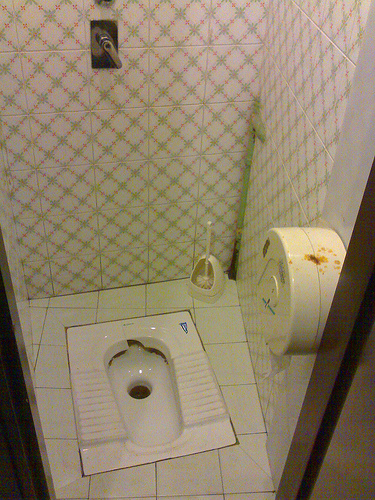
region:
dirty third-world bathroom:
[31, 26, 347, 482]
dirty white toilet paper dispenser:
[256, 199, 358, 375]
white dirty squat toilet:
[56, 302, 234, 471]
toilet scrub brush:
[186, 215, 235, 309]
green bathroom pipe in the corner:
[218, 87, 267, 300]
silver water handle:
[77, 16, 137, 89]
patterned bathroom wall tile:
[16, 72, 188, 248]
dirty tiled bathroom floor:
[28, 278, 273, 494]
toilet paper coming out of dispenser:
[255, 333, 296, 393]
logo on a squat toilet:
[168, 317, 211, 360]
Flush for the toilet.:
[84, 20, 126, 77]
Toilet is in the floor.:
[60, 326, 241, 469]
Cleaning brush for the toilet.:
[190, 218, 229, 304]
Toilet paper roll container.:
[249, 231, 306, 352]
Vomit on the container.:
[284, 224, 346, 293]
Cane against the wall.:
[220, 87, 262, 291]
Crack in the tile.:
[217, 426, 284, 490]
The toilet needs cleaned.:
[89, 335, 173, 371]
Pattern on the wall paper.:
[46, 110, 185, 221]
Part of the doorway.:
[325, 268, 373, 496]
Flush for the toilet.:
[82, 16, 135, 73]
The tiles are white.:
[151, 461, 244, 492]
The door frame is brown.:
[291, 395, 330, 490]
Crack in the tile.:
[234, 436, 273, 493]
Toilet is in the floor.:
[46, 311, 235, 472]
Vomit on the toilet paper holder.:
[287, 244, 349, 289]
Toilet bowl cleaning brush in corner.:
[171, 211, 224, 305]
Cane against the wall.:
[226, 100, 264, 284]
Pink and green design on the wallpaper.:
[54, 110, 167, 194]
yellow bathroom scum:
[285, 234, 342, 283]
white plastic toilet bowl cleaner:
[180, 203, 232, 313]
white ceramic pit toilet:
[49, 295, 257, 492]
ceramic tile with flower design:
[85, 148, 158, 219]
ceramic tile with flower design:
[141, 149, 206, 212]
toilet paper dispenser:
[235, 207, 363, 380]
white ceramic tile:
[191, 328, 262, 391]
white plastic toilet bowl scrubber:
[183, 207, 231, 317]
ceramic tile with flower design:
[95, 239, 153, 296]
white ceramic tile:
[94, 275, 153, 315]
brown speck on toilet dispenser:
[301, 243, 329, 272]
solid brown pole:
[286, 326, 341, 480]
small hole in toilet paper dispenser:
[255, 290, 276, 320]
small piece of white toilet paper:
[261, 359, 295, 387]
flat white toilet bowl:
[52, 308, 237, 491]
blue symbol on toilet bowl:
[178, 312, 193, 348]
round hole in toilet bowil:
[126, 376, 157, 414]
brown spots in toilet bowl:
[101, 335, 174, 362]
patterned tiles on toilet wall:
[45, 208, 150, 266]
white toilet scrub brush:
[199, 214, 213, 295]